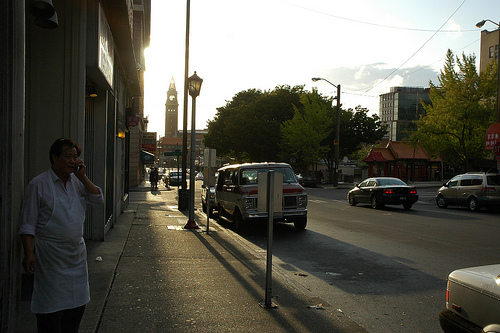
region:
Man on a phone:
[45, 131, 112, 208]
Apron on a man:
[22, 168, 131, 317]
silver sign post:
[245, 161, 307, 316]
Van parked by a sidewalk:
[205, 157, 326, 238]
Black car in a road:
[349, 171, 419, 228]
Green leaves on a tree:
[220, 81, 351, 161]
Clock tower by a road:
[160, 73, 187, 160]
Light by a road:
[304, 76, 369, 216]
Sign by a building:
[86, 8, 130, 93]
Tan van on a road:
[431, 162, 498, 197]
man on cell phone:
[38, 119, 108, 203]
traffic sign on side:
[242, 156, 309, 246]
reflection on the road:
[322, 204, 419, 265]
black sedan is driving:
[325, 163, 417, 215]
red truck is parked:
[205, 149, 291, 211]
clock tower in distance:
[169, 62, 183, 152]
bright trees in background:
[410, 55, 493, 162]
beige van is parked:
[427, 152, 492, 217]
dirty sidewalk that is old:
[125, 229, 212, 327]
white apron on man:
[24, 206, 111, 281]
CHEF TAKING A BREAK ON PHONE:
[21, 141, 98, 330]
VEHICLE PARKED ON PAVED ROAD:
[221, 169, 316, 250]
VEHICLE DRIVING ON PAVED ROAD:
[356, 161, 407, 220]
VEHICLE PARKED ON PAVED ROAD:
[433, 164, 494, 221]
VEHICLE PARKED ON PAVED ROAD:
[418, 260, 495, 313]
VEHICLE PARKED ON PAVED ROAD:
[158, 172, 196, 192]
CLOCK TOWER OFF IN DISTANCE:
[158, 60, 176, 163]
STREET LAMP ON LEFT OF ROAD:
[189, 68, 202, 241]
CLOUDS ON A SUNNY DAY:
[307, 40, 462, 85]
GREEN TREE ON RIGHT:
[422, 41, 487, 149]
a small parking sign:
[256, 168, 290, 307]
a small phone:
[73, 160, 79, 175]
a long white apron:
[30, 173, 93, 310]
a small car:
[346, 172, 424, 209]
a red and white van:
[215, 160, 314, 228]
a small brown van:
[427, 170, 495, 211]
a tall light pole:
[312, 77, 349, 184]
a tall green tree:
[419, 48, 494, 178]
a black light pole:
[187, 73, 204, 233]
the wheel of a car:
[369, 192, 381, 210]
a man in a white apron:
[21, 137, 90, 331]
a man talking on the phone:
[19, 136, 103, 331]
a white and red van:
[213, 163, 307, 231]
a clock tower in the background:
[163, 79, 178, 139]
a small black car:
[346, 176, 419, 208]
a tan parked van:
[434, 171, 499, 211]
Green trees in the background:
[206, 49, 498, 184]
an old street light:
[187, 70, 202, 230]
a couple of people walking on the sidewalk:
[150, 164, 162, 187]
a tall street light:
[313, 74, 342, 186]